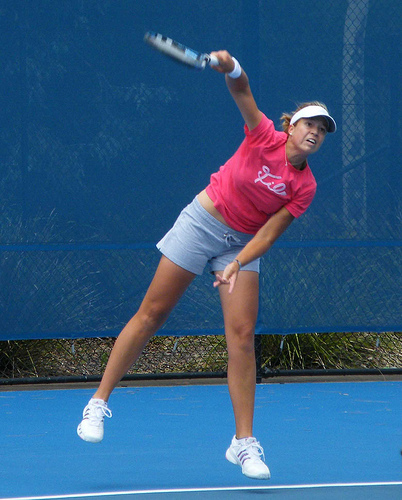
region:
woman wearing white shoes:
[51, 375, 298, 484]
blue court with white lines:
[159, 461, 322, 498]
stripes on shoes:
[222, 438, 289, 483]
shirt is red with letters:
[217, 154, 326, 229]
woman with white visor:
[266, 91, 345, 159]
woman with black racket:
[135, 23, 271, 89]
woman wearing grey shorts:
[144, 192, 282, 289]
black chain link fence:
[7, 328, 399, 392]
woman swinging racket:
[135, 21, 344, 319]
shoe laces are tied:
[214, 421, 282, 492]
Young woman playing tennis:
[64, 28, 354, 484]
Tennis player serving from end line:
[67, 23, 327, 494]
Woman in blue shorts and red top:
[146, 104, 326, 283]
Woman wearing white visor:
[273, 89, 336, 166]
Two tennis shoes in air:
[66, 382, 286, 492]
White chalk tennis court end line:
[65, 473, 400, 493]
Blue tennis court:
[3, 372, 400, 494]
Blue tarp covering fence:
[5, 12, 399, 331]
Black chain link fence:
[0, 311, 400, 385]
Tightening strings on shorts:
[217, 227, 246, 247]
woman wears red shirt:
[55, 44, 347, 493]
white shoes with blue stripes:
[74, 390, 273, 480]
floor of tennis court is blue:
[8, 366, 399, 498]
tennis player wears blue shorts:
[47, 18, 347, 483]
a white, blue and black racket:
[134, 15, 233, 75]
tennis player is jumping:
[68, 15, 350, 482]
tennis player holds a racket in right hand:
[70, 22, 345, 479]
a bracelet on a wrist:
[224, 246, 248, 276]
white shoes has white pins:
[68, 392, 281, 486]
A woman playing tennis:
[76, 21, 339, 483]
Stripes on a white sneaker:
[232, 439, 254, 470]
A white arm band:
[222, 43, 243, 87]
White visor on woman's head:
[285, 99, 340, 159]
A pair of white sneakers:
[74, 393, 276, 486]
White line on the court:
[2, 473, 399, 498]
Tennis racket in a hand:
[137, 18, 234, 78]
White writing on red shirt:
[249, 160, 290, 202]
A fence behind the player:
[1, 327, 399, 385]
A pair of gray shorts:
[152, 195, 263, 282]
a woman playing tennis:
[71, 14, 338, 480]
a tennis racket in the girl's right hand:
[140, 24, 223, 73]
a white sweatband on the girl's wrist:
[228, 54, 241, 80]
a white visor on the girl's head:
[288, 103, 341, 134]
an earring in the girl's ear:
[287, 130, 293, 138]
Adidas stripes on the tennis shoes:
[234, 447, 252, 464]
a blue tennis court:
[0, 376, 400, 498]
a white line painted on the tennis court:
[0, 476, 400, 498]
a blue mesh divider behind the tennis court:
[2, 0, 401, 335]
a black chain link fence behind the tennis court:
[0, 331, 401, 383]